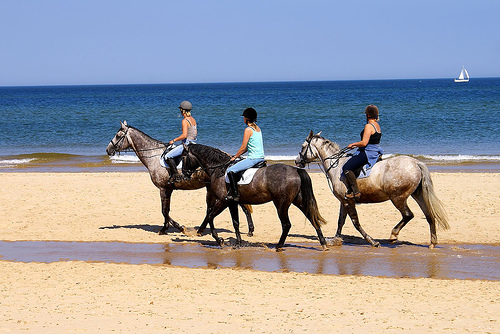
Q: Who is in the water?
A: No one.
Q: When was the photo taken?
A: Daytime.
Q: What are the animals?
A: Horses.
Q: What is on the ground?
A: Water.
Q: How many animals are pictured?
A: Three.